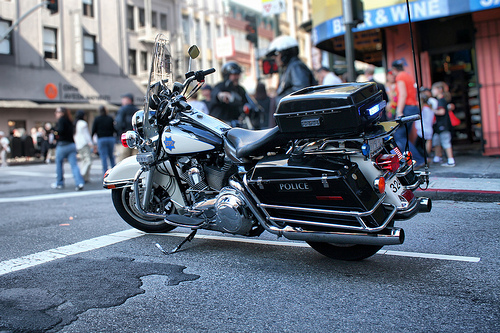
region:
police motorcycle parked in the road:
[94, 28, 444, 252]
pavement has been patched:
[39, 258, 176, 330]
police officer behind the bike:
[262, 32, 305, 92]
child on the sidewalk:
[431, 75, 459, 167]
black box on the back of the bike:
[256, 76, 381, 142]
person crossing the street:
[47, 104, 90, 189]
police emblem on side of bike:
[159, 135, 179, 152]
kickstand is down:
[154, 230, 192, 255]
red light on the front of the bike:
[114, 125, 131, 152]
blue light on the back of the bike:
[357, 142, 374, 156]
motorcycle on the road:
[62, 48, 417, 266]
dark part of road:
[4, 245, 164, 324]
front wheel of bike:
[113, 184, 167, 231]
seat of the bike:
[268, 77, 368, 122]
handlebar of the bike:
[114, 82, 196, 119]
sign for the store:
[349, 3, 451, 51]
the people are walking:
[2, 118, 102, 189]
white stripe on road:
[7, 208, 86, 286]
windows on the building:
[10, 5, 122, 78]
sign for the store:
[32, 70, 102, 101]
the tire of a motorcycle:
[108, 161, 183, 233]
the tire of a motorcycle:
[297, 183, 392, 264]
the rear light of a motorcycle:
[375, 150, 400, 175]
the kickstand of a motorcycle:
[154, 228, 203, 257]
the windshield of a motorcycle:
[141, 30, 187, 113]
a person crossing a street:
[45, 105, 85, 191]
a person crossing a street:
[90, 105, 120, 183]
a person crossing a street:
[68, 109, 108, 189]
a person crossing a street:
[106, 93, 146, 183]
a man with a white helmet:
[261, 35, 298, 63]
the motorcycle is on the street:
[115, 31, 436, 262]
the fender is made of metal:
[100, 145, 159, 190]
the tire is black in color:
[110, 183, 184, 232]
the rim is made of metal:
[121, 182, 170, 227]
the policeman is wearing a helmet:
[268, 35, 297, 63]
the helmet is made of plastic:
[264, 34, 299, 59]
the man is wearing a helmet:
[220, 61, 240, 84]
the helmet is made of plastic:
[221, 62, 242, 80]